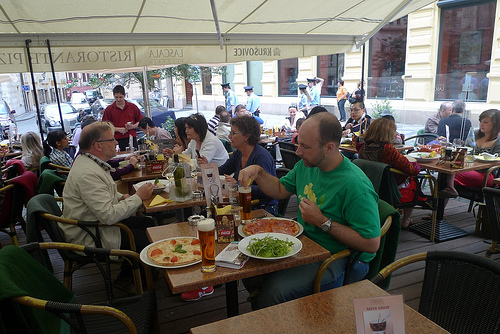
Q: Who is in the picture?
A: People.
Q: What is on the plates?
A: Food.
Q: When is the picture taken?
A: Daytime.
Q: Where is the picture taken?
A: At a restaurant.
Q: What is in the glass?
A: Beer.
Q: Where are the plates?
A: On the table.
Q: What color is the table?
A: Brown.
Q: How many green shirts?
A: One.